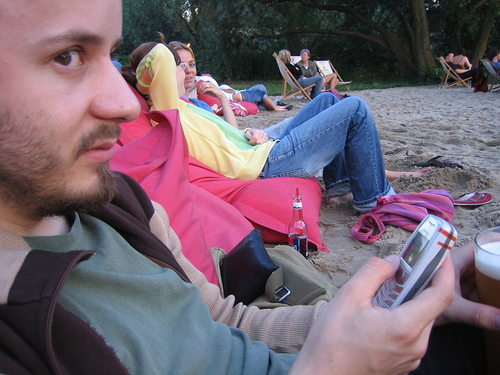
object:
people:
[1, 1, 499, 374]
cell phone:
[370, 214, 457, 309]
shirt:
[296, 60, 325, 78]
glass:
[473, 226, 500, 375]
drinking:
[473, 226, 500, 375]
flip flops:
[329, 88, 343, 100]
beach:
[232, 85, 499, 288]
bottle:
[288, 194, 310, 260]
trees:
[114, 0, 500, 85]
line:
[114, 0, 499, 83]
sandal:
[454, 191, 493, 205]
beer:
[474, 226, 500, 375]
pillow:
[187, 155, 330, 253]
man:
[0, 0, 500, 374]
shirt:
[135, 43, 280, 180]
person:
[296, 49, 339, 90]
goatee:
[69, 123, 124, 212]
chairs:
[272, 52, 315, 102]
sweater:
[134, 43, 281, 180]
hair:
[278, 49, 291, 64]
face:
[0, 0, 143, 206]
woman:
[278, 48, 323, 102]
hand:
[291, 253, 455, 375]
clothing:
[350, 188, 454, 244]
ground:
[218, 84, 500, 288]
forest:
[111, 0, 500, 84]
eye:
[52, 49, 83, 68]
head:
[300, 49, 310, 61]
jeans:
[259, 92, 397, 213]